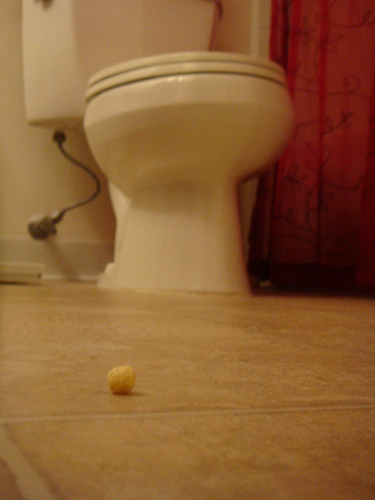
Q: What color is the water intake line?
A: Silver.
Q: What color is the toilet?
A: White.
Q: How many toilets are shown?
A: One.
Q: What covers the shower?
A: Curtain.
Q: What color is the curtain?
A: Burgundy.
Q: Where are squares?
A: Floor.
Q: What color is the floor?
A: Tan.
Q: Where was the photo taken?
A: The bathroom.